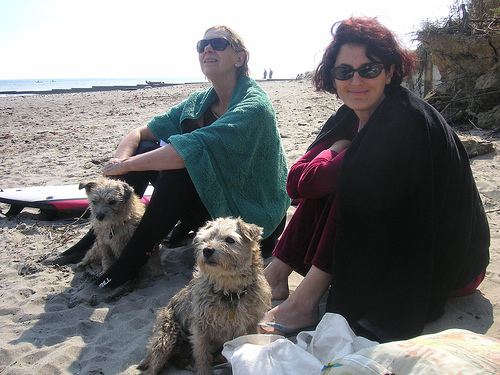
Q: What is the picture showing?
A: It is showing a beach.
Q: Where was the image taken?
A: It was taken at the beach.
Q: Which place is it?
A: It is a beach.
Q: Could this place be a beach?
A: Yes, it is a beach.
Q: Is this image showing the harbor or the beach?
A: It is showing the beach.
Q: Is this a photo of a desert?
A: No, the picture is showing a beach.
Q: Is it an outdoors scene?
A: Yes, it is outdoors.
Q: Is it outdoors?
A: Yes, it is outdoors.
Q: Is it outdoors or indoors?
A: It is outdoors.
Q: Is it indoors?
A: No, it is outdoors.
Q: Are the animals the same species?
A: Yes, all the animals are dogs.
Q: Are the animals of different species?
A: No, all the animals are dogs.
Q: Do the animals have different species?
A: No, all the animals are dogs.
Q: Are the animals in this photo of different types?
A: No, all the animals are dogs.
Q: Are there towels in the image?
A: Yes, there is a towel.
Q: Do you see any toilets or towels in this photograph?
A: Yes, there is a towel.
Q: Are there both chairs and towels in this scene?
A: No, there is a towel but no chairs.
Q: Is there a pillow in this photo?
A: No, there are no pillows.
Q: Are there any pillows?
A: No, there are no pillows.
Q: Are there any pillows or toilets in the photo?
A: No, there are no pillows or toilets.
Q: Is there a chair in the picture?
A: No, there are no chairs.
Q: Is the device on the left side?
A: Yes, the device is on the left of the image.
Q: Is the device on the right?
A: No, the device is on the left of the image.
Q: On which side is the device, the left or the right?
A: The device is on the left of the image.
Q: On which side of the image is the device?
A: The device is on the left of the image.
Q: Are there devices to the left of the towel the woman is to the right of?
A: Yes, there is a device to the left of the towel.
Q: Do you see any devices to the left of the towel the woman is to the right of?
A: Yes, there is a device to the left of the towel.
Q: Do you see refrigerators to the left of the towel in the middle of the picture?
A: No, there is a device to the left of the towel.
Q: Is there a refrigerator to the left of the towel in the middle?
A: No, there is a device to the left of the towel.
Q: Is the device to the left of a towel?
A: Yes, the device is to the left of a towel.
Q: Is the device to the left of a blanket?
A: No, the device is to the left of a towel.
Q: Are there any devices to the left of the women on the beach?
A: Yes, there is a device to the left of the women.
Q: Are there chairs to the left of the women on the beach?
A: No, there is a device to the left of the women.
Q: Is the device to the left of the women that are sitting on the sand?
A: Yes, the device is to the left of the women.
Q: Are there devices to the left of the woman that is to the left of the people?
A: Yes, there is a device to the left of the woman.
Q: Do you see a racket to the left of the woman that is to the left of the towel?
A: No, there is a device to the left of the woman.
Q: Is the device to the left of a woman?
A: Yes, the device is to the left of a woman.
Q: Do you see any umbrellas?
A: No, there are no umbrellas.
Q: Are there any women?
A: Yes, there are women.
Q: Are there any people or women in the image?
A: Yes, there are women.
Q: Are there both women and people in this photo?
A: Yes, there are both women and people.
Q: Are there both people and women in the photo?
A: Yes, there are both women and people.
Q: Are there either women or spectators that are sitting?
A: Yes, the women are sitting.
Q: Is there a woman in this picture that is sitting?
A: Yes, there are women that are sitting.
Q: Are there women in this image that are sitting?
A: Yes, there are women that are sitting.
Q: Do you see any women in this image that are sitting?
A: Yes, there are women that are sitting.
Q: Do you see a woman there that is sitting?
A: Yes, there are women that are sitting.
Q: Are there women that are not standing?
A: Yes, there are women that are sitting.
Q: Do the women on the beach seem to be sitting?
A: Yes, the women are sitting.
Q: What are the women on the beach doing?
A: The women are sitting.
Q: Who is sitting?
A: The women are sitting.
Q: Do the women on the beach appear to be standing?
A: No, the women are sitting.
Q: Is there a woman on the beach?
A: Yes, there are women on the beach.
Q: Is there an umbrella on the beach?
A: No, there are women on the beach.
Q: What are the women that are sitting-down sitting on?
A: The women are sitting on the sand.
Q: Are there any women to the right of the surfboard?
A: Yes, there are women to the right of the surfboard.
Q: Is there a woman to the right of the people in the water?
A: Yes, there are women to the right of the people.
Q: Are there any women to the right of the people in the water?
A: Yes, there are women to the right of the people.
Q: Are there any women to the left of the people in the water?
A: No, the women are to the right of the people.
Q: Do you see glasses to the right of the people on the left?
A: No, there are women to the right of the people.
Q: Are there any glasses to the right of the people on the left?
A: No, there are women to the right of the people.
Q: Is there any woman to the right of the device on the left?
A: Yes, there are women to the right of the device.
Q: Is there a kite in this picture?
A: No, there are no kites.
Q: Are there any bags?
A: Yes, there is a bag.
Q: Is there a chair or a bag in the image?
A: Yes, there is a bag.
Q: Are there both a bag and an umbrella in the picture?
A: No, there is a bag but no umbrellas.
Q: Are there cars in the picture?
A: No, there are no cars.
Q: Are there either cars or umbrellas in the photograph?
A: No, there are no cars or umbrellas.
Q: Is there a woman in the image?
A: Yes, there is a woman.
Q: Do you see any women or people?
A: Yes, there is a woman.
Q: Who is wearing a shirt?
A: The woman is wearing a shirt.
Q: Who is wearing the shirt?
A: The woman is wearing a shirt.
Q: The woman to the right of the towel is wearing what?
A: The woman is wearing a shirt.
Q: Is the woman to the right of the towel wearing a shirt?
A: Yes, the woman is wearing a shirt.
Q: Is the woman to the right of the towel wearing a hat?
A: No, the woman is wearing a shirt.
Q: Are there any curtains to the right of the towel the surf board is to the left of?
A: No, there is a woman to the right of the towel.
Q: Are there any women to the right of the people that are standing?
A: Yes, there is a woman to the right of the people.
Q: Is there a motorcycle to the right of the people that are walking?
A: No, there is a woman to the right of the people.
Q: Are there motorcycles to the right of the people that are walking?
A: No, there is a woman to the right of the people.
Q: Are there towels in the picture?
A: Yes, there is a towel.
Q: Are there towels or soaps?
A: Yes, there is a towel.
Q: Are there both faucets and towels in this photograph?
A: No, there is a towel but no faucets.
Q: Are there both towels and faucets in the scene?
A: No, there is a towel but no faucets.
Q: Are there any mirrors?
A: No, there are no mirrors.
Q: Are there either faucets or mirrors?
A: No, there are no mirrors or faucets.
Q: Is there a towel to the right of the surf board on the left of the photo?
A: Yes, there is a towel to the right of the surfboard.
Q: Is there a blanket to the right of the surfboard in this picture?
A: No, there is a towel to the right of the surfboard.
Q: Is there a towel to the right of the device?
A: Yes, there is a towel to the right of the device.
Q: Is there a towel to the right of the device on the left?
A: Yes, there is a towel to the right of the device.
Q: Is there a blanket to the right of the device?
A: No, there is a towel to the right of the device.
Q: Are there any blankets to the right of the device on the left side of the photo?
A: No, there is a towel to the right of the device.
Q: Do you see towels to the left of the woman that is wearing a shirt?
A: Yes, there is a towel to the left of the woman.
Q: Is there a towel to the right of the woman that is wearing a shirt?
A: No, the towel is to the left of the woman.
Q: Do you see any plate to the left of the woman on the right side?
A: No, there is a towel to the left of the woman.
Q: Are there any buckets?
A: No, there are no buckets.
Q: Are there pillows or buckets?
A: No, there are no buckets or pillows.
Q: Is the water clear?
A: Yes, the water is clear.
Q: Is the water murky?
A: No, the water is clear.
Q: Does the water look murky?
A: No, the water is clear.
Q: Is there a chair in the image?
A: No, there are no chairs.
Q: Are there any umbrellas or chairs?
A: No, there are no chairs or umbrellas.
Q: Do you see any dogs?
A: Yes, there is a dog.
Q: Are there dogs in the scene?
A: Yes, there is a dog.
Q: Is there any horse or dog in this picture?
A: Yes, there is a dog.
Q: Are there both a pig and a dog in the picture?
A: No, there is a dog but no pigs.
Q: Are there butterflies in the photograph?
A: No, there are no butterflies.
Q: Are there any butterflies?
A: No, there are no butterflies.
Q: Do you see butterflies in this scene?
A: No, there are no butterflies.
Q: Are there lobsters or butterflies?
A: No, there are no butterflies or lobsters.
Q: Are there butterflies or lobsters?
A: No, there are no butterflies or lobsters.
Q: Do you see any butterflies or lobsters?
A: No, there are no butterflies or lobsters.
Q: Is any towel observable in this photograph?
A: Yes, there is a towel.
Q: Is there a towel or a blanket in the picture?
A: Yes, there is a towel.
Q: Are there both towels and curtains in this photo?
A: No, there is a towel but no curtains.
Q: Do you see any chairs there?
A: No, there are no chairs.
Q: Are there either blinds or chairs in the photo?
A: No, there are no chairs or blinds.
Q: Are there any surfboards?
A: Yes, there is a surfboard.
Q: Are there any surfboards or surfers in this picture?
A: Yes, there is a surfboard.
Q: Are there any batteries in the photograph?
A: No, there are no batteries.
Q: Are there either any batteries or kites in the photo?
A: No, there are no batteries or kites.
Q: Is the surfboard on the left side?
A: Yes, the surfboard is on the left of the image.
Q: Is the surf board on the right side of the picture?
A: No, the surf board is on the left of the image.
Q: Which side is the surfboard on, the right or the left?
A: The surfboard is on the left of the image.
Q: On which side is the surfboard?
A: The surfboard is on the left of the image.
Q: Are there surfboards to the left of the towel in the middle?
A: Yes, there is a surfboard to the left of the towel.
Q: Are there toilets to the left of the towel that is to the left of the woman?
A: No, there is a surfboard to the left of the towel.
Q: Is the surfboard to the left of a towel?
A: Yes, the surfboard is to the left of a towel.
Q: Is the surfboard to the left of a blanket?
A: No, the surfboard is to the left of a towel.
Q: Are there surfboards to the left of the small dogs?
A: Yes, there is a surfboard to the left of the dogs.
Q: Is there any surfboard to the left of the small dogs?
A: Yes, there is a surfboard to the left of the dogs.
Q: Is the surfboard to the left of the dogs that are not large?
A: Yes, the surfboard is to the left of the dogs.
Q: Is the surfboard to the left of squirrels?
A: No, the surfboard is to the left of the dogs.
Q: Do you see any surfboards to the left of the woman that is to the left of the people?
A: Yes, there is a surfboard to the left of the woman.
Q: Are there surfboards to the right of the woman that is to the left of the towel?
A: No, the surfboard is to the left of the woman.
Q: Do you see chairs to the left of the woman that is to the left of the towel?
A: No, there is a surfboard to the left of the woman.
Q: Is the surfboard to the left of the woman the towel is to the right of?
A: Yes, the surfboard is to the left of the woman.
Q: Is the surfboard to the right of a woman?
A: No, the surfboard is to the left of a woman.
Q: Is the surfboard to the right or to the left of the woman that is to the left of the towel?
A: The surfboard is to the left of the woman.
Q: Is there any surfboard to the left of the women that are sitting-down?
A: Yes, there is a surfboard to the left of the women.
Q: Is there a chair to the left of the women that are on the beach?
A: No, there is a surfboard to the left of the women.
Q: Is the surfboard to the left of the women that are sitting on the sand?
A: Yes, the surfboard is to the left of the women.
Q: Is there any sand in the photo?
A: Yes, there is sand.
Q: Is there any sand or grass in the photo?
A: Yes, there is sand.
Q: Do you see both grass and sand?
A: No, there is sand but no grass.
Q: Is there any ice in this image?
A: No, there is no ice.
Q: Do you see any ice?
A: No, there is no ice.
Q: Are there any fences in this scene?
A: No, there are no fences.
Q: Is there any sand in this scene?
A: Yes, there is sand.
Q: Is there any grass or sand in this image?
A: Yes, there is sand.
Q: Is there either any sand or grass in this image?
A: Yes, there is sand.